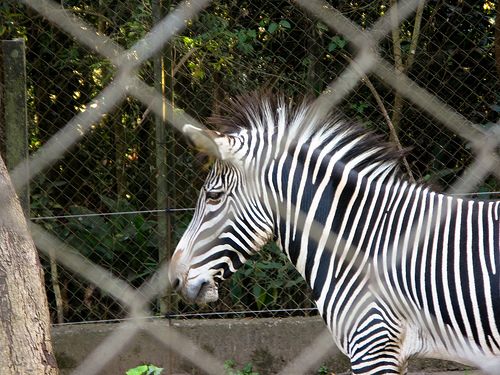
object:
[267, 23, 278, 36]
leaves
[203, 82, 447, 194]
mane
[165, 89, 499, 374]
zebra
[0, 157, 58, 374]
trunk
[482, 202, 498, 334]
stripe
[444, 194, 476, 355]
black stripe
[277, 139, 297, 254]
black stripe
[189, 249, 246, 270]
black stripe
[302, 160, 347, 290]
black stripe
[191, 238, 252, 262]
stripe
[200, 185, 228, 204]
eye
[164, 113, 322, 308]
head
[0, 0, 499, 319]
bush